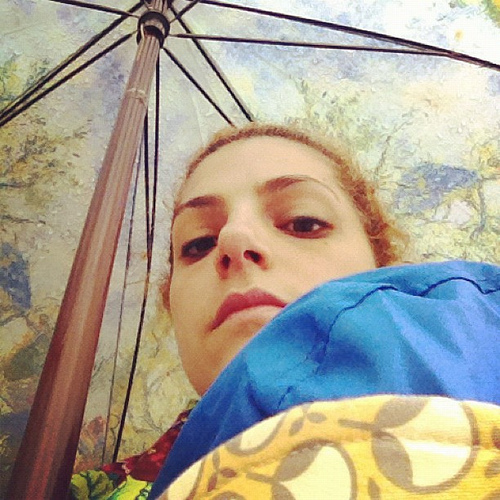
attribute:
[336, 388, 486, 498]
flower — black, white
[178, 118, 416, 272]
hair — light colored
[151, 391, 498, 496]
jacket — yellow, brown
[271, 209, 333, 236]
eye — brown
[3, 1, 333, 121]
stem — brown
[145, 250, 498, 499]
material — puffy, blue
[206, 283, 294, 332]
lip — pink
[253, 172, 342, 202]
eyebrow — light brown, arched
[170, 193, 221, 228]
eyebrow — light brown, arched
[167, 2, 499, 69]
stem — black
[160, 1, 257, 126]
stem — black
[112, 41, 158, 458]
stem — black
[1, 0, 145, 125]
stem — black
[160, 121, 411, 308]
hair — light brown, curly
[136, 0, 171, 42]
joint — umbrella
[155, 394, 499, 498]
blanket — yellow, flower patterned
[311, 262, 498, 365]
shoulder — coat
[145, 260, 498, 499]
coat — blue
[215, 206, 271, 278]
nose — female, caucasian, pointy, pointed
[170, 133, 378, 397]
face — girls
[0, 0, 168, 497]
pole — umbrella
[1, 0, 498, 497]
umbrella — colorful, open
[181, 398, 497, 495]
fabric — yellow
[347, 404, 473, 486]
leaf — brown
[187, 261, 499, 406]
cloth — blue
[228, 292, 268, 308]
lipstick — red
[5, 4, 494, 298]
umbrella — large, decorative, open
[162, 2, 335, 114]
frame — wire, brown, dark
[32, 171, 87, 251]
drops — rain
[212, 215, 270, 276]
nose — pointy, fair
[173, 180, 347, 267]
eyes — brown, dark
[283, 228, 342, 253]
lines — small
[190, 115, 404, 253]
hair — blond, red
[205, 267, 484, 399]
shirt — blue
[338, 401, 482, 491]
pattern — yellow, painted, blue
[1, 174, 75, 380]
pattern — floral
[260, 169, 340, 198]
eyebrow — thin, brown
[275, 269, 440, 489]
fabric — pattern